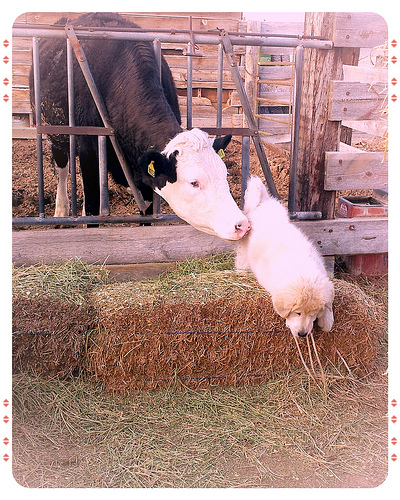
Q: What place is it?
A: It is a field.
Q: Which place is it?
A: It is a field.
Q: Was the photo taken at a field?
A: Yes, it was taken in a field.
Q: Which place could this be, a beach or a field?
A: It is a field.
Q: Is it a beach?
A: No, it is a field.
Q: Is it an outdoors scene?
A: Yes, it is outdoors.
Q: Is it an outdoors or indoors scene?
A: It is outdoors.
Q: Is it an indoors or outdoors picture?
A: It is outdoors.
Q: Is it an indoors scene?
A: No, it is outdoors.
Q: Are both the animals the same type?
A: No, they are dogs and cows.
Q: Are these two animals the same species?
A: No, they are dogs and cows.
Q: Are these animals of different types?
A: Yes, they are dogs and cows.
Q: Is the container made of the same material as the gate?
A: Yes, both the container and the gate are made of metal.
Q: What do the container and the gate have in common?
A: The material, both the container and the gate are metallic.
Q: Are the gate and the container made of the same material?
A: Yes, both the gate and the container are made of metal.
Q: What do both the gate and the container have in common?
A: The material, both the gate and the container are metallic.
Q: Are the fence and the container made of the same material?
A: No, the fence is made of wood and the container is made of metal.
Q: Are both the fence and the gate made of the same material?
A: No, the fence is made of wood and the gate is made of metal.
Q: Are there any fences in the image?
A: Yes, there is a fence.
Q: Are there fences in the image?
A: Yes, there is a fence.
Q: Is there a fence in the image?
A: Yes, there is a fence.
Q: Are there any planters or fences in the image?
A: Yes, there is a fence.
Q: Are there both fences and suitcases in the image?
A: No, there is a fence but no suitcases.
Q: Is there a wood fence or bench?
A: Yes, there is a wood fence.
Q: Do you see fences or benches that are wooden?
A: Yes, the fence is wooden.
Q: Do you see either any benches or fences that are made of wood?
A: Yes, the fence is made of wood.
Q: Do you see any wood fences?
A: Yes, there is a wood fence.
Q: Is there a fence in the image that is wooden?
A: Yes, there is a fence that is wooden.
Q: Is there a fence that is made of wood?
A: Yes, there is a fence that is made of wood.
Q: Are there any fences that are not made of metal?
A: Yes, there is a fence that is made of wood.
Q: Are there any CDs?
A: No, there are no cds.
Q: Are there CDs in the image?
A: No, there are no cds.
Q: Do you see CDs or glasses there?
A: No, there are no CDs or glasses.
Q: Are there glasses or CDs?
A: No, there are no CDs or glasses.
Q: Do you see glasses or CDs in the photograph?
A: No, there are no CDs or glasses.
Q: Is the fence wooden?
A: Yes, the fence is wooden.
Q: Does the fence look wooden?
A: Yes, the fence is wooden.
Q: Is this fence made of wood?
A: Yes, the fence is made of wood.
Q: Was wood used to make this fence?
A: Yes, the fence is made of wood.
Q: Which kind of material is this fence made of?
A: The fence is made of wood.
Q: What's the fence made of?
A: The fence is made of wood.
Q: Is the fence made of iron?
A: No, the fence is made of wood.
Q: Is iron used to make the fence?
A: No, the fence is made of wood.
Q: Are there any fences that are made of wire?
A: No, there is a fence but it is made of wood.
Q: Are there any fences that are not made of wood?
A: No, there is a fence but it is made of wood.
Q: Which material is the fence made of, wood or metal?
A: The fence is made of wood.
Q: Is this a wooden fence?
A: Yes, this is a wooden fence.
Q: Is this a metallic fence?
A: No, this is a wooden fence.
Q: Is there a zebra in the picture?
A: No, there are no zebras.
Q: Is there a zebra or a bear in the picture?
A: No, there are no zebras or bears.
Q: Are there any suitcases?
A: No, there are no suitcases.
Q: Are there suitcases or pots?
A: No, there are no suitcases or pots.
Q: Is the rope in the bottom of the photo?
A: Yes, the rope is in the bottom of the image.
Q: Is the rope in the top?
A: No, the rope is in the bottom of the image.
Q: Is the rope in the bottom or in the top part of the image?
A: The rope is in the bottom of the image.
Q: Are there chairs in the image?
A: No, there are no chairs.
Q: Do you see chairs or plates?
A: No, there are no chairs or plates.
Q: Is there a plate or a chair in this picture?
A: No, there are no chairs or plates.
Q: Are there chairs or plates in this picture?
A: No, there are no chairs or plates.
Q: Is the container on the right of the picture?
A: Yes, the container is on the right of the image.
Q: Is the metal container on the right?
A: Yes, the container is on the right of the image.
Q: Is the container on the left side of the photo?
A: No, the container is on the right of the image.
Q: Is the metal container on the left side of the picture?
A: No, the container is on the right of the image.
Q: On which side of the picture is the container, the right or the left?
A: The container is on the right of the image.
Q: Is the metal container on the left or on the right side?
A: The container is on the right of the image.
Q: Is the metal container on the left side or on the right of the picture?
A: The container is on the right of the image.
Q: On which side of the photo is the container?
A: The container is on the right of the image.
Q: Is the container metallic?
A: Yes, the container is metallic.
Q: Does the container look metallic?
A: Yes, the container is metallic.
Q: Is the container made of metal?
A: Yes, the container is made of metal.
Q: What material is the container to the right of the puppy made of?
A: The container is made of metal.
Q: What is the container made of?
A: The container is made of metal.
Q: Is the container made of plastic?
A: No, the container is made of metal.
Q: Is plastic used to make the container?
A: No, the container is made of metal.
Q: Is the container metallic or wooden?
A: The container is metallic.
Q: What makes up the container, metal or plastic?
A: The container is made of metal.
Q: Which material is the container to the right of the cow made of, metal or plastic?
A: The container is made of metal.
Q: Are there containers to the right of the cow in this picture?
A: Yes, there is a container to the right of the cow.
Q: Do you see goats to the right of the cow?
A: No, there is a container to the right of the cow.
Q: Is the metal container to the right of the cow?
A: Yes, the container is to the right of the cow.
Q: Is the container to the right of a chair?
A: No, the container is to the right of the cow.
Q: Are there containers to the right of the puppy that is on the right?
A: Yes, there is a container to the right of the puppy.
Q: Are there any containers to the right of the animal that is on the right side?
A: Yes, there is a container to the right of the puppy.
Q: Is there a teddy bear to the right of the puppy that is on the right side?
A: No, there is a container to the right of the puppy.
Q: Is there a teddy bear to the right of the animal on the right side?
A: No, there is a container to the right of the puppy.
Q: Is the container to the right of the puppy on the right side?
A: Yes, the container is to the right of the puppy.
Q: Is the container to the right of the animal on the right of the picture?
A: Yes, the container is to the right of the puppy.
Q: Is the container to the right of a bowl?
A: No, the container is to the right of the puppy.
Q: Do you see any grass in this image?
A: Yes, there is grass.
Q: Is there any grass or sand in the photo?
A: Yes, there is grass.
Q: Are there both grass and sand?
A: No, there is grass but no sand.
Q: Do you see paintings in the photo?
A: No, there are no paintings.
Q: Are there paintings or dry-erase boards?
A: No, there are no paintings or dry-erase boards.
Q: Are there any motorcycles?
A: No, there are no motorcycles.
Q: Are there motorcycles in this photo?
A: No, there are no motorcycles.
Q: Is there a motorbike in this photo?
A: No, there are no motorcycles.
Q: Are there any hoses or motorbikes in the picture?
A: No, there are no motorbikes or hoses.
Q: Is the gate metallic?
A: Yes, the gate is metallic.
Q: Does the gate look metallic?
A: Yes, the gate is metallic.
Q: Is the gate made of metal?
A: Yes, the gate is made of metal.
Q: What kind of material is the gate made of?
A: The gate is made of metal.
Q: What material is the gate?
A: The gate is made of metal.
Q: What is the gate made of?
A: The gate is made of metal.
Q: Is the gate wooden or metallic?
A: The gate is metallic.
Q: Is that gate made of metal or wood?
A: The gate is made of metal.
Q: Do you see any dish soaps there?
A: No, there are no dish soaps.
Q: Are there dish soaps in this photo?
A: No, there are no dish soaps.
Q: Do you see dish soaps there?
A: No, there are no dish soaps.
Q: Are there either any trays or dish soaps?
A: No, there are no dish soaps or trays.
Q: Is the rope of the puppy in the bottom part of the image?
A: Yes, the rope is in the bottom of the image.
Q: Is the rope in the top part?
A: No, the rope is in the bottom of the image.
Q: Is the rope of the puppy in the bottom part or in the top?
A: The rope is in the bottom of the image.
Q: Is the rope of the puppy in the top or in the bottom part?
A: The rope is in the bottom of the image.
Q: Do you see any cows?
A: Yes, there is a cow.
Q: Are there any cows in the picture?
A: Yes, there is a cow.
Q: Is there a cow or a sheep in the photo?
A: Yes, there is a cow.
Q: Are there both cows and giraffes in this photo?
A: No, there is a cow but no giraffes.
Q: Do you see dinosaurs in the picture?
A: No, there are no dinosaurs.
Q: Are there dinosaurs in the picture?
A: No, there are no dinosaurs.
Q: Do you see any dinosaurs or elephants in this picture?
A: No, there are no dinosaurs or elephants.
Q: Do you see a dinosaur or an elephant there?
A: No, there are no dinosaurs or elephants.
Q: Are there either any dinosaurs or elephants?
A: No, there are no dinosaurs or elephants.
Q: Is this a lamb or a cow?
A: This is a cow.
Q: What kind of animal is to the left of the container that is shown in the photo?
A: The animal is a cow.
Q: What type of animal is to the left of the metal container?
A: The animal is a cow.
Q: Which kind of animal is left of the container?
A: The animal is a cow.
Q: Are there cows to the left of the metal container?
A: Yes, there is a cow to the left of the container.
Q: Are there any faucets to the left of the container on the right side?
A: No, there is a cow to the left of the container.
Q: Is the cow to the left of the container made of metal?
A: Yes, the cow is to the left of the container.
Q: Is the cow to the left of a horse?
A: No, the cow is to the left of the container.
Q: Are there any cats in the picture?
A: No, there are no cats.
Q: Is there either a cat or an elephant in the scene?
A: No, there are no cats or elephants.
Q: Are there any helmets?
A: No, there are no helmets.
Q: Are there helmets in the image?
A: No, there are no helmets.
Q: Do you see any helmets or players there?
A: No, there are no helmets or players.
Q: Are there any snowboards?
A: No, there are no snowboards.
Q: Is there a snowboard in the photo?
A: No, there are no snowboards.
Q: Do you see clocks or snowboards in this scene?
A: No, there are no snowboards or clocks.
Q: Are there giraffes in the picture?
A: No, there are no giraffes.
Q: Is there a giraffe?
A: No, there are no giraffes.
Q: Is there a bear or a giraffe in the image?
A: No, there are no giraffes or bears.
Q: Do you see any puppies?
A: Yes, there is a puppy.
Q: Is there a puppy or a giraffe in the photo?
A: Yes, there is a puppy.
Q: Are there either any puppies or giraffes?
A: Yes, there is a puppy.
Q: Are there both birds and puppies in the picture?
A: No, there is a puppy but no birds.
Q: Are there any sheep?
A: No, there are no sheep.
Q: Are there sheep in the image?
A: No, there are no sheep.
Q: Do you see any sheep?
A: No, there are no sheep.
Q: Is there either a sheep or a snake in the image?
A: No, there are no sheep or snakes.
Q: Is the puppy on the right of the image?
A: Yes, the puppy is on the right of the image.